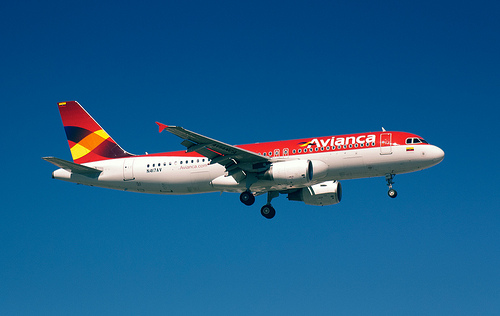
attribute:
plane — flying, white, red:
[43, 101, 448, 219]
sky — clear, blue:
[1, 2, 498, 314]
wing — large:
[154, 119, 271, 184]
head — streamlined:
[398, 129, 446, 175]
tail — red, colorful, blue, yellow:
[55, 98, 130, 165]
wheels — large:
[240, 190, 278, 221]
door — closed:
[380, 132, 392, 157]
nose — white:
[430, 143, 445, 168]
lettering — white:
[311, 136, 376, 145]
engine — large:
[262, 159, 314, 185]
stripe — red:
[72, 130, 430, 160]